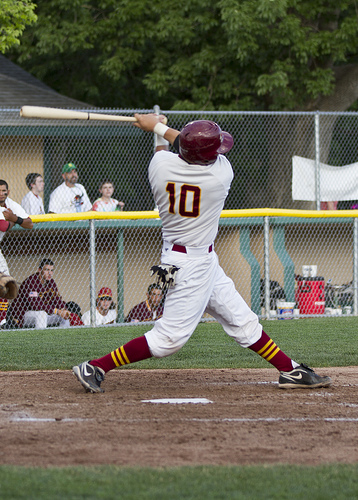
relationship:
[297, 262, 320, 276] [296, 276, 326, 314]
cups on top of cooler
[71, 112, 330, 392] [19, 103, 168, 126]
man swinging bat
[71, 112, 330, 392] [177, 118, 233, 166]
man wearing helmet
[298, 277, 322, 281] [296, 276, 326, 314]
black lid covering cooler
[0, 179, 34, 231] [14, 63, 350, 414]
spectators watching baseball game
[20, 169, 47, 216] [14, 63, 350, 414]
spectators watching baseball game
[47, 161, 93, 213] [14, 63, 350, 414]
man watching baseball game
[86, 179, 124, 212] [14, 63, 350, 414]
spectators watching baseball game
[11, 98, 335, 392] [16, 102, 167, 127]
man swinging baseball bat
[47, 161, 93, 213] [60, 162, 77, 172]
man wearing green hat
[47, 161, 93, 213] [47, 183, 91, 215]
man wearing white t-shirt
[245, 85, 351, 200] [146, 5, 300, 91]
trunk of tree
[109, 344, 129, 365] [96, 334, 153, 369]
yellow stripes on red stirrups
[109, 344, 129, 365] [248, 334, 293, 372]
yellow stripes on red stirrups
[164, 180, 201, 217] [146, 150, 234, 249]
10 on jersey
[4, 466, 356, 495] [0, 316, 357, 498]
grass on baseball field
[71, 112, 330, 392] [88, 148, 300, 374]
man wears uniform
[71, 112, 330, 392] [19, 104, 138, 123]
man holding bat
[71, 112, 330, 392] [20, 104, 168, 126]
man swinging a baseball bat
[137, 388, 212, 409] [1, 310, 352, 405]
plate on baseball field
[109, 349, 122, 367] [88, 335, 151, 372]
yellow stripes on sock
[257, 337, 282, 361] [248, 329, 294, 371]
stripes on red sock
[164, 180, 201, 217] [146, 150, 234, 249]
10 written on back of jersey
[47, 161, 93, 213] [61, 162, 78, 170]
man wearing green cap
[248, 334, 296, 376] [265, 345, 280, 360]
red sock with stripes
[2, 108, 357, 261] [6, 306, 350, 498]
fence at field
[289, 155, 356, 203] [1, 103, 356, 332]
banner on fence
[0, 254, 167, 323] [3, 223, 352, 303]
players sitting in dugout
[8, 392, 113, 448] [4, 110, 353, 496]
dirt on baseball field